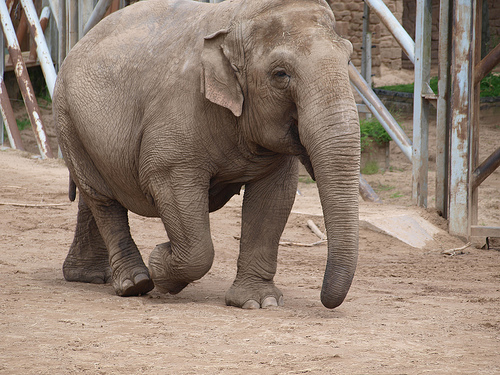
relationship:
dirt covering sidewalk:
[364, 249, 491, 294] [359, 203, 441, 242]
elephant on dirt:
[51, 0, 363, 312] [336, 327, 453, 359]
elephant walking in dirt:
[52, 6, 372, 313] [1, 100, 498, 372]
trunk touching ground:
[292, 63, 364, 313] [4, 99, 497, 373]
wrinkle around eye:
[262, 52, 297, 93] [272, 67, 292, 82]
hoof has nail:
[223, 273, 286, 310] [241, 299, 259, 312]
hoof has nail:
[223, 273, 286, 310] [259, 293, 276, 307]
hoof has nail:
[223, 273, 286, 310] [277, 293, 287, 307]